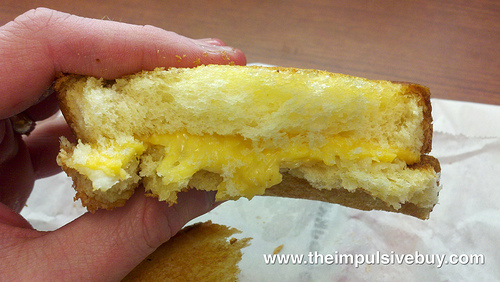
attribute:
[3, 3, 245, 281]
hand — white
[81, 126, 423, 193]
melted cheese — melted 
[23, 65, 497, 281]
white surface — paper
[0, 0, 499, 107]
table — wooden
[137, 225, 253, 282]
bread — flaky, torn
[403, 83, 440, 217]
crust — brown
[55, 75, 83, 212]
crust — dark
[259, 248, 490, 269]
writing — white, website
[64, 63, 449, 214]
sandwich — toasted, melted cheese, white, middle  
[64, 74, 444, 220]
bread — two slices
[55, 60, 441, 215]
bread — two pieces